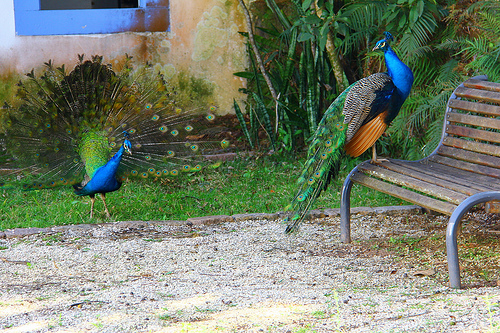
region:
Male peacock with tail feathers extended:
[1, 50, 226, 228]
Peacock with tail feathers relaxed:
[283, 29, 413, 238]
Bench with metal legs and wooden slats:
[430, 70, 497, 286]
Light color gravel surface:
[63, 240, 315, 323]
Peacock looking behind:
[363, 29, 412, 104]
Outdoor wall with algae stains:
[189, 0, 246, 109]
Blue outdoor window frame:
[11, 0, 175, 33]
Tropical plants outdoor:
[240, 1, 312, 145]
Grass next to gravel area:
[222, 157, 267, 257]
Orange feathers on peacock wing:
[344, 111, 390, 158]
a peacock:
[270, 49, 400, 185]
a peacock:
[289, 53, 360, 135]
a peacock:
[273, 13, 488, 165]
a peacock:
[319, 74, 441, 204]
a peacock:
[291, 76, 402, 288]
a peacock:
[239, 121, 494, 282]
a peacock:
[253, 99, 393, 223]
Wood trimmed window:
[7, 1, 184, 48]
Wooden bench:
[314, 42, 497, 257]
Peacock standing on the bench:
[265, 30, 420, 245]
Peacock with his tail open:
[2, 37, 237, 238]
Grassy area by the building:
[0, 155, 413, 220]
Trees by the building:
[229, 1, 474, 166]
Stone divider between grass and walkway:
[0, 199, 449, 241]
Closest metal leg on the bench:
[424, 176, 499, 305]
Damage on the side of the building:
[114, 7, 281, 144]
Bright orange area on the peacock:
[343, 96, 408, 178]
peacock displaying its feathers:
[10, 50, 256, 250]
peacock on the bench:
[265, 27, 430, 243]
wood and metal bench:
[315, 46, 497, 291]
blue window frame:
[1, 1, 191, 41]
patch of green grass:
[0, 145, 411, 221]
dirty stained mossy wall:
[116, 20, 251, 125]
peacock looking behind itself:
[270, 18, 432, 255]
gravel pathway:
[6, 211, 486, 331]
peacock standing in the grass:
[12, 42, 250, 272]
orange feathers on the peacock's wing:
[340, 97, 405, 166]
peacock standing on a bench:
[280, 20, 495, 268]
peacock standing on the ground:
[19, 50, 240, 249]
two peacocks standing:
[17, 18, 427, 262]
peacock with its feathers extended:
[4, 33, 222, 227]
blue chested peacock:
[291, 14, 419, 256]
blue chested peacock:
[26, 46, 205, 218]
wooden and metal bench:
[375, 67, 495, 225]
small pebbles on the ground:
[53, 228, 327, 326]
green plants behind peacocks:
[237, 0, 318, 147]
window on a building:
[10, 0, 179, 67]